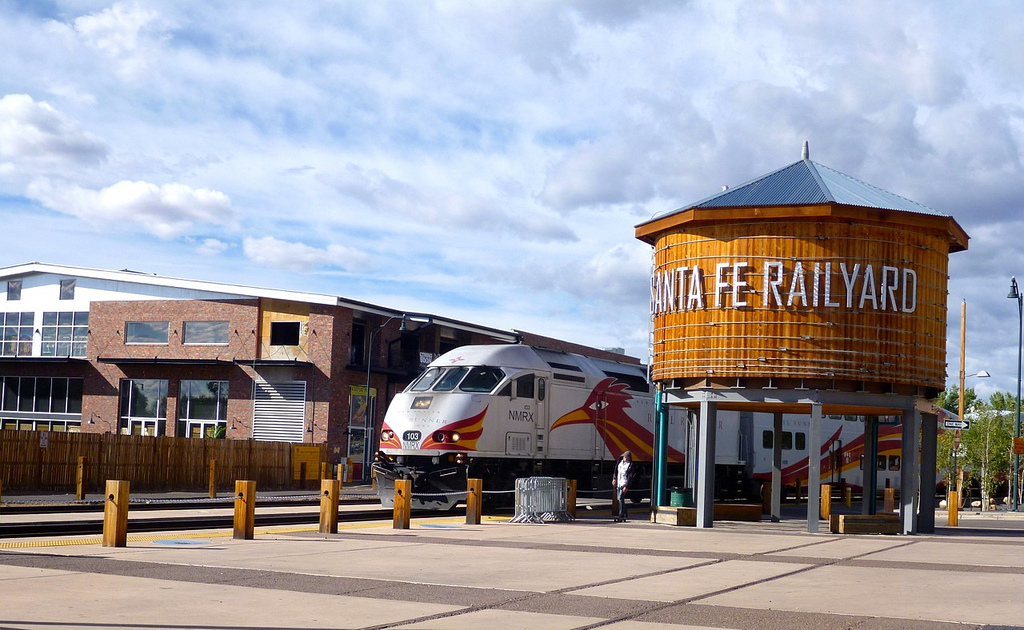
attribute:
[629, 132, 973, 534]
water tower — Sante Fe Railyard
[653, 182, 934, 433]
tower — water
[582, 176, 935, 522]
tower — water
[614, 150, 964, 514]
tower — water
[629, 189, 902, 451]
tower — water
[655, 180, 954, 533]
tower — water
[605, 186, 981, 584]
tower — water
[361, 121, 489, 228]
clouds — white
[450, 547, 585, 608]
ground — brown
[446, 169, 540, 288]
cloud — white, fluffy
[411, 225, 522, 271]
cloud — fluffy, white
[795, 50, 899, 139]
cloud — white, fluffy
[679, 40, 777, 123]
cloud — fluffy, white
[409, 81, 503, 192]
cloud — white, fluffy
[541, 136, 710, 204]
cloud — fluffy, gray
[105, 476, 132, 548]
post — small, yellow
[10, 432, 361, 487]
fence — wooden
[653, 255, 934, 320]
letterings — white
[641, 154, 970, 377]
tank — wooden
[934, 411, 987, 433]
sign — small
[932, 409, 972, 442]
arrow — white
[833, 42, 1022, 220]
cloud — grey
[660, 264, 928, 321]
name — place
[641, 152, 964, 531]
tower — big, for water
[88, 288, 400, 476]
building — brick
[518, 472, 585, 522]
box — small, metal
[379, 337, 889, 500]
train — colorful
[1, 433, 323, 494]
fence — wooden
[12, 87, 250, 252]
cloud — white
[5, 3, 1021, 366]
sky — blue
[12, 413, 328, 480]
fence — surrounding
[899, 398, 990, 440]
sign — one way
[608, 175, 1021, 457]
tower — white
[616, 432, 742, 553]
can — green